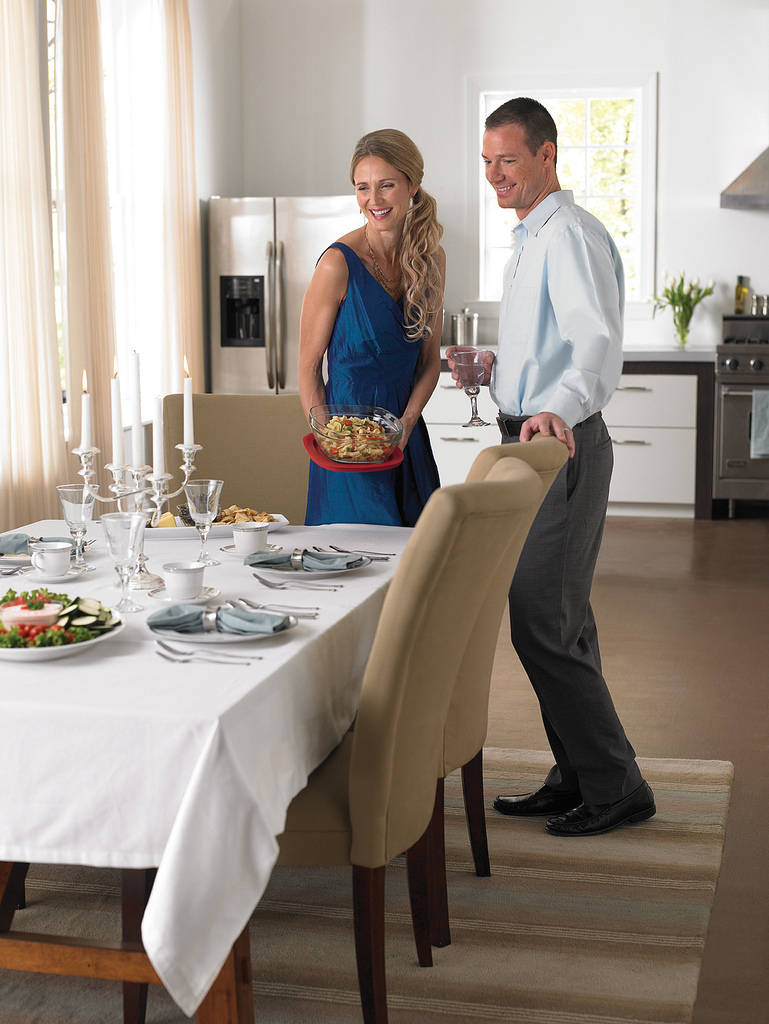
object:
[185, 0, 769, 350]
wall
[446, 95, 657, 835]
person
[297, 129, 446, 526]
person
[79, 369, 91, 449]
candle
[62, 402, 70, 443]
candle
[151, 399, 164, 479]
candle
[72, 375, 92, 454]
candle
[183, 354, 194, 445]
candle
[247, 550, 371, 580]
plate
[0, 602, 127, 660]
plate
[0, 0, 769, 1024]
building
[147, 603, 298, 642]
plate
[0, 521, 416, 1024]
table